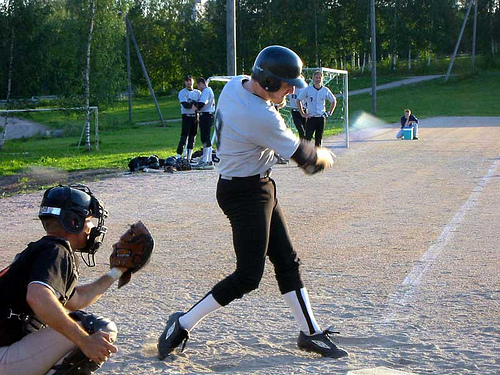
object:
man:
[153, 43, 351, 362]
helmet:
[249, 43, 308, 92]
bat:
[303, 111, 394, 176]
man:
[395, 109, 421, 140]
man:
[295, 70, 337, 147]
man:
[190, 77, 216, 168]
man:
[175, 74, 202, 164]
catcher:
[0, 179, 153, 375]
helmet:
[38, 183, 102, 235]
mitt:
[108, 220, 156, 290]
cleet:
[294, 330, 350, 361]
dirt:
[247, 348, 265, 363]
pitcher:
[403, 126, 414, 141]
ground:
[0, 116, 500, 375]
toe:
[162, 352, 168, 356]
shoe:
[156, 310, 186, 362]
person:
[396, 109, 419, 140]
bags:
[126, 154, 160, 172]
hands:
[302, 113, 312, 119]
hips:
[316, 117, 326, 126]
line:
[383, 160, 499, 323]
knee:
[237, 268, 264, 292]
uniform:
[177, 88, 202, 155]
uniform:
[194, 86, 215, 148]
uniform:
[209, 73, 321, 306]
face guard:
[69, 185, 110, 268]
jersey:
[214, 74, 301, 178]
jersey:
[178, 87, 203, 115]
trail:
[377, 82, 437, 97]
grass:
[0, 54, 499, 197]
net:
[330, 120, 342, 139]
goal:
[302, 66, 350, 149]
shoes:
[292, 324, 349, 360]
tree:
[46, 0, 125, 147]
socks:
[185, 149, 194, 161]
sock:
[280, 287, 320, 335]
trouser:
[210, 169, 306, 307]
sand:
[306, 193, 403, 264]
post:
[224, 0, 241, 76]